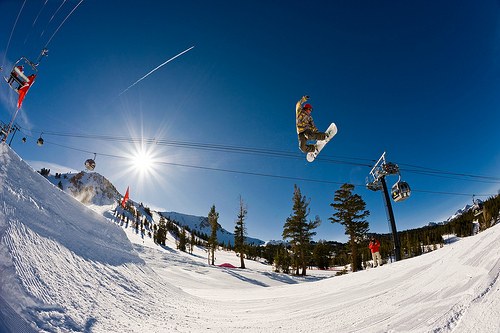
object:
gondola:
[391, 174, 412, 203]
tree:
[281, 183, 322, 275]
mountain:
[36, 170, 231, 254]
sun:
[128, 148, 158, 177]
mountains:
[157, 211, 293, 249]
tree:
[326, 181, 372, 273]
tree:
[310, 239, 326, 269]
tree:
[232, 192, 253, 269]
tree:
[207, 203, 222, 265]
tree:
[178, 225, 188, 251]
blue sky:
[0, 0, 500, 244]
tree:
[336, 251, 348, 266]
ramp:
[0, 143, 232, 333]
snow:
[0, 141, 500, 333]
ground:
[0, 140, 500, 333]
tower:
[364, 151, 401, 263]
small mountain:
[37, 170, 123, 208]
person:
[369, 235, 384, 268]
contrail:
[116, 45, 194, 97]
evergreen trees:
[327, 181, 370, 272]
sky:
[0, 0, 500, 245]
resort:
[110, 197, 500, 282]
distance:
[0, 0, 500, 245]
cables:
[18, 130, 497, 197]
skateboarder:
[306, 122, 338, 163]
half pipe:
[0, 139, 500, 332]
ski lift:
[84, 159, 97, 171]